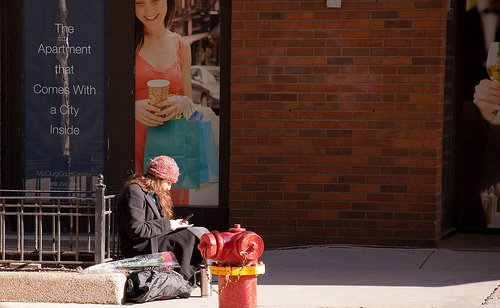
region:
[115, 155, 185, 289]
Roses lying next to woman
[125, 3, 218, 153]
Billboard of woman shopping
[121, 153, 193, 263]
Woman sitting and writing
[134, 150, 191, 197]
Woman wearing red cap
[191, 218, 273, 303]
Red and yellow fire hydrant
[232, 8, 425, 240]
Red brick wall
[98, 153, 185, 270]
Woman sitting against black railing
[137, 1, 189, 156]
Woman holding paper coffee cup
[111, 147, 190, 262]
Woman in black coat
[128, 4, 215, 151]
Woman with blue shopping bag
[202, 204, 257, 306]
Fire hydrant on the sidewalk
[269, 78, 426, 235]
Brick wall in the background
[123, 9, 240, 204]
Large banner near the wall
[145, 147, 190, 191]
Beanie on girls head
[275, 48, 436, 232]
The brick is different colors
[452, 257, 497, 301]
Crack on the sidewalk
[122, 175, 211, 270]
Woman wearing a winter coat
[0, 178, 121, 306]
Metal fence near sidewalk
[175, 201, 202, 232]
The woman is holding a cellphone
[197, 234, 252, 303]
chains on side of fire hydrant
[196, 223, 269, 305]
red fire hydrant with yellow strip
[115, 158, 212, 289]
woman sitting on a curbside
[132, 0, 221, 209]
poster of a woman with coffee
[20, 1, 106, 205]
poster with an apartment advertisement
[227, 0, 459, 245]
brick building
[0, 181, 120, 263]
metal gate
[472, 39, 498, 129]
picture of a person's hand holding a glass of wine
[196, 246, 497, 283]
shadow from the building on the ground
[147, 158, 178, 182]
beanie on the woman's head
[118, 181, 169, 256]
black coat on the woman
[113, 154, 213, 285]
a girl wearing a black coat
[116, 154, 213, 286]
a girl wearing a red hat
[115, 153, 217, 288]
a girl holding a phone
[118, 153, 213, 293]
a girl with long brown hair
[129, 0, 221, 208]
a sign with a woman holding bags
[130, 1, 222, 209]
a woman with a cup on a sign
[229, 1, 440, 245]
a big brick wall beside a sign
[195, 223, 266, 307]
a red fire hydrant by the sidewalk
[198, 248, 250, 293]
a chain on a fire hydrant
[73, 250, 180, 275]
a bouquet of roses in plastic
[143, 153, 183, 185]
pink hat on the girls head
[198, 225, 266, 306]
red fire hydrant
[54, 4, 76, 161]
reflection in the grass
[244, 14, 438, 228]
red brick wall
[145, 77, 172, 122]
cup in the woman's hand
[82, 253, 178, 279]
red roses resting on the backpack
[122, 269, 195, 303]
black back pack on the ground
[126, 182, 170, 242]
woman's right arm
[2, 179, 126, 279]
metal railing woman is leaning against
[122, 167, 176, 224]
the woman's long brown hair